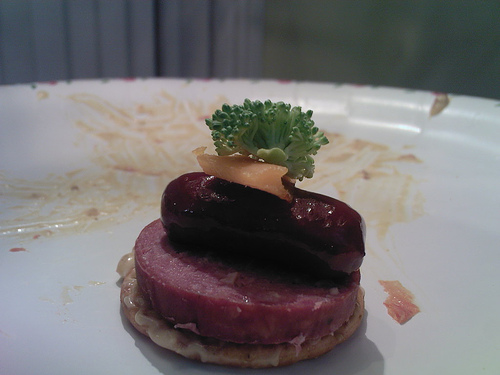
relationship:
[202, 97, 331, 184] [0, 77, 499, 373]
broccoli on dish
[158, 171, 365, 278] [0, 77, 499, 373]
ham on dish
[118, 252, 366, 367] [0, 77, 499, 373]
cracker on dish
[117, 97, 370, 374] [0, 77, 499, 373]
food on dish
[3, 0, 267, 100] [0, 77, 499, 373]
blinds behind dish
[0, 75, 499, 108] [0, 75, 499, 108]
plate edge on plate edge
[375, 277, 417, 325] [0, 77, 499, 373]
sauce on dish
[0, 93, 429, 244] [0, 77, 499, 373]
sauce on dish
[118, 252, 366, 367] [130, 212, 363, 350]
cracker under meat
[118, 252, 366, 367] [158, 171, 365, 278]
cracker under ham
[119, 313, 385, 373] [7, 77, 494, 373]
shadow cast on dish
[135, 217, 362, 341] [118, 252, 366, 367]
meat on cracker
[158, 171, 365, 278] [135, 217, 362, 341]
ham on meat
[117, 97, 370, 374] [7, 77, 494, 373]
food on dish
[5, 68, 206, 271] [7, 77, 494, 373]
stains are on dish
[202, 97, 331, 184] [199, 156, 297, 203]
broccoli on cheese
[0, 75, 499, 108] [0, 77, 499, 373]
plate edge on dish